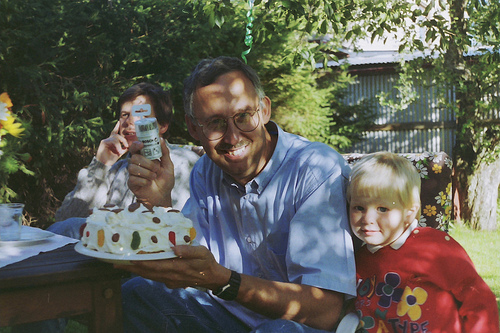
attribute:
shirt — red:
[343, 147, 496, 330]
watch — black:
[215, 270, 266, 324]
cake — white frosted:
[76, 206, 200, 260]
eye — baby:
[378, 196, 390, 215]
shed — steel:
[305, 52, 499, 181]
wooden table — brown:
[0, 225, 125, 330]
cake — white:
[76, 211, 193, 263]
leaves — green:
[55, 33, 142, 79]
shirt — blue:
[181, 126, 362, 320]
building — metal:
[319, 47, 485, 224]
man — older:
[112, 53, 359, 329]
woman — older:
[47, 79, 202, 235]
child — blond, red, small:
[343, 151, 498, 331]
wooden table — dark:
[20, 270, 64, 295]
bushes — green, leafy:
[12, 20, 112, 137]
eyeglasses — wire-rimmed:
[205, 106, 265, 127]